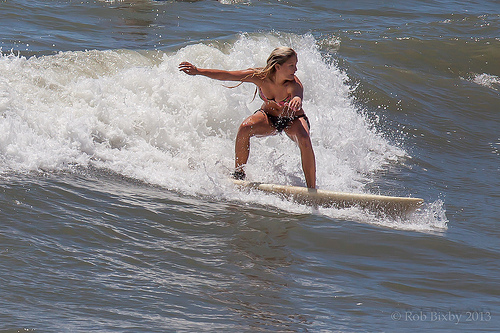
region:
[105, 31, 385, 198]
A woman surfing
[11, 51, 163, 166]
White topped waves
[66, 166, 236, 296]
Sun reflecting off the water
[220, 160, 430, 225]
A surfboard on the water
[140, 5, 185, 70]
Water spray shooting up from the waves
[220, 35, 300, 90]
Wet blond hair caught in the wind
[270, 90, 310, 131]
Water dripping from a woman's hand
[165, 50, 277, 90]
A woman's arm held out to steady herself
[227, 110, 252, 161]
Sunlight glistening off of wet skin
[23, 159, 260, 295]
Water calming down after the wave breaks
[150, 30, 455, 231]
a blonde girl surfing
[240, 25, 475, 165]
A wave breaking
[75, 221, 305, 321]
murky shore break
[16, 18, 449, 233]
a girl in a bikini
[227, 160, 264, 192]
a surfboard leash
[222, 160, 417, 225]
a white, short surfboard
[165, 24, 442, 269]
a young woman using her arms for balance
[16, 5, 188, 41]
glassy sea water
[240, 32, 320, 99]
a girl with sun bleached hair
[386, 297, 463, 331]
a photographer's watermark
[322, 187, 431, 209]
part of white surfboard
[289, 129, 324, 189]
ladies leg on surfboard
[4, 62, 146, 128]
portion of a foamy wave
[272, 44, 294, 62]
blond hair on surfer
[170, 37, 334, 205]
female surfer in big wave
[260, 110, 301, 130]
black bikini bottom on lady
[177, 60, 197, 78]
hand of female surfer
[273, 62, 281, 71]
ear on female surfer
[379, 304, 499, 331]
copyright sign of photographer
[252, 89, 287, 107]
top portion of bikini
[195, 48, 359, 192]
an attractive girl surfing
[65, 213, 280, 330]
water in the ocean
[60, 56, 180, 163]
waves caused by water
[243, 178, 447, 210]
a white surfboard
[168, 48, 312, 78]
the girls face and arm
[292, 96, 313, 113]
the girls hand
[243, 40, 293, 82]
the surfers blonde hair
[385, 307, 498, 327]
Rob Bixby 2013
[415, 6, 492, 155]
calm water in the ocean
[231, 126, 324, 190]
the knees for the girl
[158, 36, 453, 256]
The woman is surfing.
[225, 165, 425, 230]
The surfboard is white.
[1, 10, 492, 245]
The woman is riding a wave.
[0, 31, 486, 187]
A wave is behind the woman.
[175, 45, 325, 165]
The woman's arms are out.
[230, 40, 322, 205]
The woman is wearing a bikini.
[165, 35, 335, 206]
The woman is crouching on the board.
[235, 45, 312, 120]
The woman has dirty blonde hair.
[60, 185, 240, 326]
The water is a grayish-blue color.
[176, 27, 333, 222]
The woman has a tan.